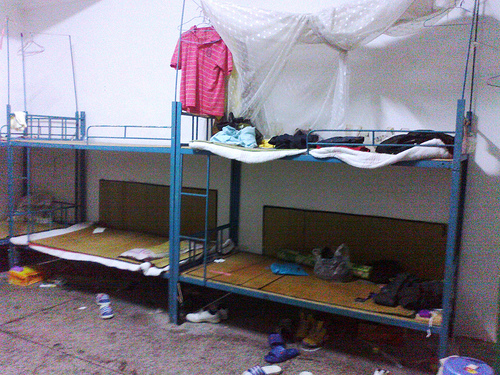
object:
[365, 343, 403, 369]
scene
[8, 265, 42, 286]
box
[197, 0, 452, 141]
sheet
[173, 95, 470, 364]
bed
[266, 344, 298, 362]
sandals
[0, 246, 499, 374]
floor